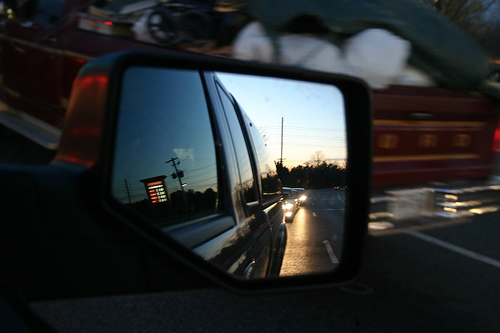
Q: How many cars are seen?
A: 3.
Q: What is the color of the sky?
A: Blue.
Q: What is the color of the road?
A: Grey.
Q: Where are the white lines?
A: In the road.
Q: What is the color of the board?
A: Red.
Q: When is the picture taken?
A: Night time.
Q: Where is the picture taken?
A: In an automobile.